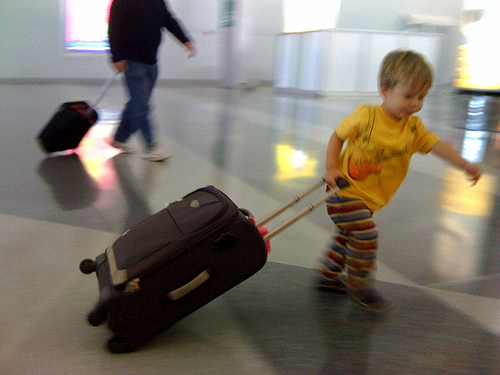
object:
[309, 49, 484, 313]
child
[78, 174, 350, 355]
suitcase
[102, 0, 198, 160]
adult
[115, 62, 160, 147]
jeans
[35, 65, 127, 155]
suitcase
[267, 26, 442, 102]
counters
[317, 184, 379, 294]
pants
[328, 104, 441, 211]
top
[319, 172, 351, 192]
handle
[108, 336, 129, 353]
wheel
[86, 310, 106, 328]
wheel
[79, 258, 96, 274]
wheel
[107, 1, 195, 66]
top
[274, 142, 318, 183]
area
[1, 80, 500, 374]
floor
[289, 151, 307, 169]
circle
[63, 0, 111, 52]
window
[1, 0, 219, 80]
wall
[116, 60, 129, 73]
handle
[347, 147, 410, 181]
guitar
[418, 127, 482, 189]
left arm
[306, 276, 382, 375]
shadow